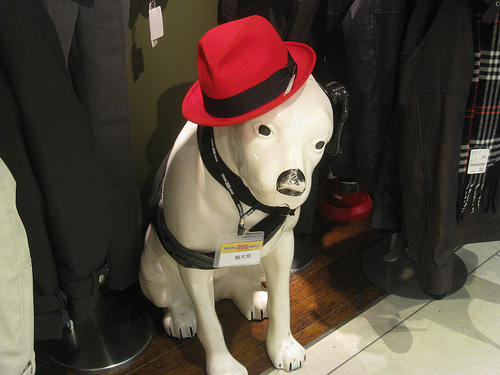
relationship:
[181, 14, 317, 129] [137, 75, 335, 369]
hat on top of dog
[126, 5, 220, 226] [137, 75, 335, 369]
wall behind dog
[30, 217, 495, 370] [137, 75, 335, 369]
ground underneath dog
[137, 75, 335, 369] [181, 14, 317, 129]
dog wearing a hat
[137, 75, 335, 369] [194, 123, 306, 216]
dog has neck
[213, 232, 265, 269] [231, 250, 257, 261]
tag has name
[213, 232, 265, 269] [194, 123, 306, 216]
tag around neck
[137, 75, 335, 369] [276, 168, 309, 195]
dog has nose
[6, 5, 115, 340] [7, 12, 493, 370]
coat inside of a store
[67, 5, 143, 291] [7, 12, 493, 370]
trouser inside of a store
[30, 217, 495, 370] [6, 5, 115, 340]
ground underneath coat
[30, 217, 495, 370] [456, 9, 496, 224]
ground underneath scarf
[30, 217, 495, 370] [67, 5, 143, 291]
ground underneath trouser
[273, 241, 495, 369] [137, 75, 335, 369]
tile in front of dog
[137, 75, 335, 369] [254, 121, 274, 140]
dog has an eye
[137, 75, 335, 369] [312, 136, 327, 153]
dog has an eye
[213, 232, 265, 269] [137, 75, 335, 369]
tag for dog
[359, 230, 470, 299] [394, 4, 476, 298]
stand for jacket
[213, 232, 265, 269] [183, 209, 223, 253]
tag has shadow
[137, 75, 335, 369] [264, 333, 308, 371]
dog has paw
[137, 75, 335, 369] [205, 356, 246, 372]
dog has paw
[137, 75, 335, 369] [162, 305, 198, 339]
dog has paw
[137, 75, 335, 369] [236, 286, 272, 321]
dog has paw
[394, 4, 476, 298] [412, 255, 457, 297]
jacket has cuff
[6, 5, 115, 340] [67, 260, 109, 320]
coat has cuff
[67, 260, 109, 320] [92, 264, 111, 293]
cuff has link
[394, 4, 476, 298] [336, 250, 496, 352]
jacket has shadow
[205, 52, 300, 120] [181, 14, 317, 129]
ribbon around base of hat